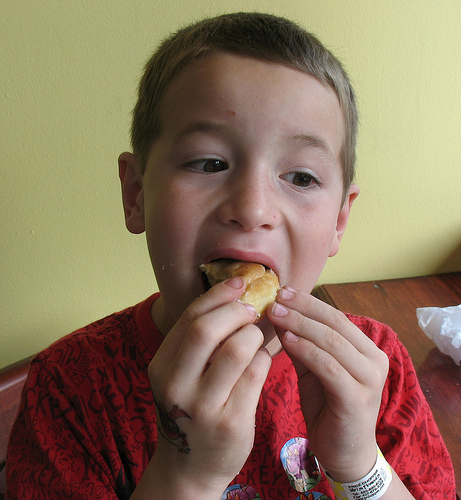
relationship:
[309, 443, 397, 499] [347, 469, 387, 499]
tag has writing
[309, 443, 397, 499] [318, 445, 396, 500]
tag on wrist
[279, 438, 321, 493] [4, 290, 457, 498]
sticker on shirt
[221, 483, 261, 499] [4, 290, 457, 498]
sticker on shirt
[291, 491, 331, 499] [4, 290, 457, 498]
sticker on shirt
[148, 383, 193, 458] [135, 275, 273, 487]
artwork on hand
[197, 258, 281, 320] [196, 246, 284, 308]
food stuffed in mouth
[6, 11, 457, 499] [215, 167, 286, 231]
boy has nose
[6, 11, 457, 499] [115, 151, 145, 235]
boy has ear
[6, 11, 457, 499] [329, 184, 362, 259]
boy has ear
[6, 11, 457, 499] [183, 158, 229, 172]
boy has eye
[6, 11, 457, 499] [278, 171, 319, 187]
boy has eye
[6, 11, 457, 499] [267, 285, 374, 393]
boy has fingers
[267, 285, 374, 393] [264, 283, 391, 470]
fingers on hand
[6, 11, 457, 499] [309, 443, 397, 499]
boy wearing tag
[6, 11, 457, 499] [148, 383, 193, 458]
boy has artwork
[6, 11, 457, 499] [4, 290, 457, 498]
boy wearing shirt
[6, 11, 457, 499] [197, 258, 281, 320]
boy eating food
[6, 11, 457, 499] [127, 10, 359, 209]
boy has hair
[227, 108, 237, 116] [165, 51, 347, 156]
scratch on forehead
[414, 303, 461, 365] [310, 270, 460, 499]
bag on table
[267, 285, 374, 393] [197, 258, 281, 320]
fingers pushing food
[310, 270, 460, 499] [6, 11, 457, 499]
table near boy